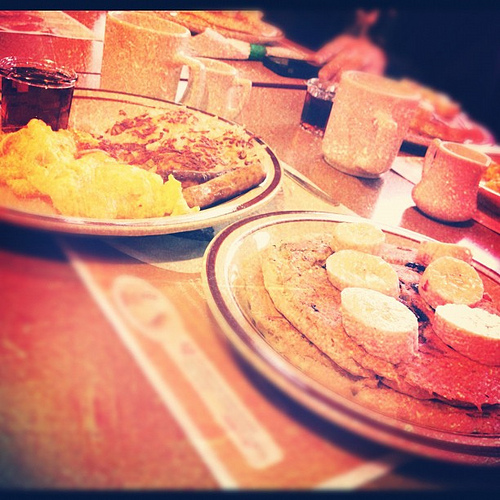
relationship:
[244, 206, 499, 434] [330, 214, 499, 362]
pancake with bananas